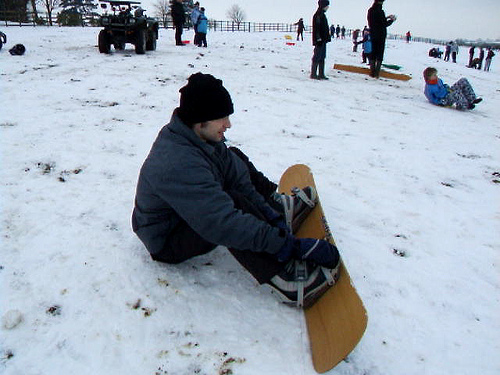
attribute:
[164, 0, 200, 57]
adult — standing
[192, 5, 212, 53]
children — standing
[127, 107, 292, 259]
jacket — grey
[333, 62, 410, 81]
object — wooden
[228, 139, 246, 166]
knee — bent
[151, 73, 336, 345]
man — seated, young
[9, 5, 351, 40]
fencing — long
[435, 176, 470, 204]
dark holes — small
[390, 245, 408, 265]
dark holes — small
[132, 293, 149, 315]
dark holes — small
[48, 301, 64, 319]
dark holes — small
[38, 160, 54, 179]
dark holes — small